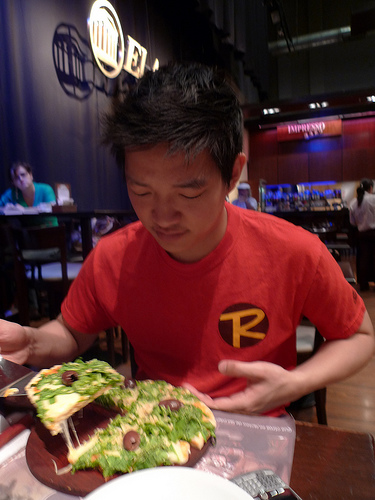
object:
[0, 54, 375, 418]
person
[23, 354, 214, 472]
pizza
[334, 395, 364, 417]
floor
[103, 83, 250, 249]
head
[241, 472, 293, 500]
phone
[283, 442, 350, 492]
table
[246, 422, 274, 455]
cover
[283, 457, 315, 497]
wood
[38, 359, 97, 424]
food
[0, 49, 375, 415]
man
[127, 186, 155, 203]
eye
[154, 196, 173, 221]
nsoe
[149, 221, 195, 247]
mouth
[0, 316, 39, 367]
hand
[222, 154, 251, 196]
ear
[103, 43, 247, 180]
hair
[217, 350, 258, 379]
thumb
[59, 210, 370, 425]
shirt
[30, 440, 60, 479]
board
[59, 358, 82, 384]
stone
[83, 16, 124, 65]
letter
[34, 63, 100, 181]
wall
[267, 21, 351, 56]
light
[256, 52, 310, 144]
ceiling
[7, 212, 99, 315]
chair